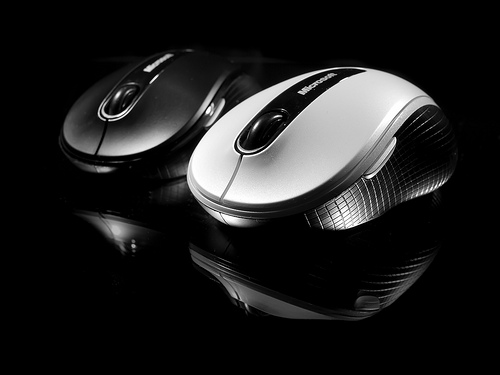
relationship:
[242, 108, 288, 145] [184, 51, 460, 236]
part of a mouse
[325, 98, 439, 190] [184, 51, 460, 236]
edge of a mouse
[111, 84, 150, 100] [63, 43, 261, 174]
part of mouse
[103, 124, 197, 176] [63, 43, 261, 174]
edge of a mouse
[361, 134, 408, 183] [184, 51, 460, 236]
part of a mouse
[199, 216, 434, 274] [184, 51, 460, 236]
bottom of mouse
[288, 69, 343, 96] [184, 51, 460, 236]
microsoft computer mouse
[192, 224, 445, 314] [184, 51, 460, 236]
reflection of mouse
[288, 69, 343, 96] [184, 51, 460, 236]
logo on mouse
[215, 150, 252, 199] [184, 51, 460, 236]
break on mouse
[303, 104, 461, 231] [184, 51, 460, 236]
curve of mouse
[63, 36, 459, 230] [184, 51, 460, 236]
display of mouse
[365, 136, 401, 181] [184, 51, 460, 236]
button on mouse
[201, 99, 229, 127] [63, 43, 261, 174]
button on mouse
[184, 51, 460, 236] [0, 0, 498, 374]
mouse on desk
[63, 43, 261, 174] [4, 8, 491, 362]
mouse on desk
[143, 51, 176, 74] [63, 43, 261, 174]
logo on mouse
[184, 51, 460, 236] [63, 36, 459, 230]
mouse on display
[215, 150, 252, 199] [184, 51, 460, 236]
line in mouse